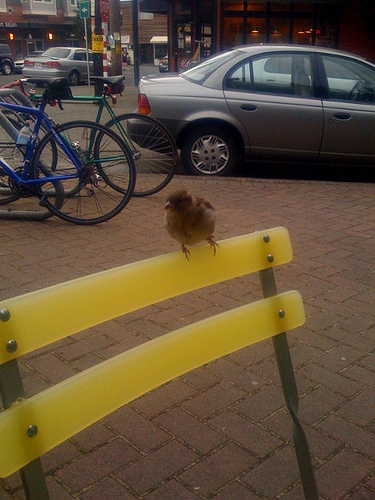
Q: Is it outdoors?
A: Yes, it is outdoors.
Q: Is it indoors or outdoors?
A: It is outdoors.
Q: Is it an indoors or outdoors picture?
A: It is outdoors.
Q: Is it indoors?
A: No, it is outdoors.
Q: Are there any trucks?
A: No, there are no trucks.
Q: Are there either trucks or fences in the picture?
A: No, there are no trucks or fences.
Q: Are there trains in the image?
A: No, there are no trains.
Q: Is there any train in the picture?
A: No, there are no trains.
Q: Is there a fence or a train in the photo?
A: No, there are no trains or fences.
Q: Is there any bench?
A: Yes, there is a bench.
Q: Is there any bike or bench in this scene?
A: Yes, there is a bench.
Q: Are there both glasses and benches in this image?
A: No, there is a bench but no glasses.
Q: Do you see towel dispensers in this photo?
A: No, there are no towel dispensers.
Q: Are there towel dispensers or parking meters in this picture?
A: No, there are no towel dispensers or parking meters.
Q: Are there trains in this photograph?
A: No, there are no trains.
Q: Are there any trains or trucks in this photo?
A: No, there are no trains or trucks.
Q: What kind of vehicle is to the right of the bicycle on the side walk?
A: The vehicle is a car.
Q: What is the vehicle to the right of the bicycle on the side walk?
A: The vehicle is a car.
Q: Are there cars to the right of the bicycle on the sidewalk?
A: Yes, there is a car to the right of the bicycle.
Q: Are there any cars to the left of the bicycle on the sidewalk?
A: No, the car is to the right of the bicycle.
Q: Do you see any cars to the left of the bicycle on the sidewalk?
A: No, the car is to the right of the bicycle.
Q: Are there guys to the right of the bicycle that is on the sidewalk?
A: No, there is a car to the right of the bicycle.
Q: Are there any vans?
A: No, there are no vans.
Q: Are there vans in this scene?
A: No, there are no vans.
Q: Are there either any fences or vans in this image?
A: No, there are no vans or fences.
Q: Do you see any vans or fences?
A: No, there are no vans or fences.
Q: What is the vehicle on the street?
A: The vehicle is a car.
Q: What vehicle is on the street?
A: The vehicle is a car.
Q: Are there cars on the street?
A: Yes, there is a car on the street.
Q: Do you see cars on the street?
A: Yes, there is a car on the street.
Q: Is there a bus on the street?
A: No, there is a car on the street.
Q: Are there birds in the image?
A: Yes, there is a bird.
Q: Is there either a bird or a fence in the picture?
A: Yes, there is a bird.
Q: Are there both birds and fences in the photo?
A: No, there is a bird but no fences.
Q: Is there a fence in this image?
A: No, there are no fences.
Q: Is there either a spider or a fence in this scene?
A: No, there are no fences or spiders.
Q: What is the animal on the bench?
A: The animal is a bird.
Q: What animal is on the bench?
A: The animal is a bird.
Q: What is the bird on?
A: The bird is on the bench.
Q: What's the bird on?
A: The bird is on the bench.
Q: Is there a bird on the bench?
A: Yes, there is a bird on the bench.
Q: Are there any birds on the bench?
A: Yes, there is a bird on the bench.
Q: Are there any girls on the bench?
A: No, there is a bird on the bench.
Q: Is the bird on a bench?
A: Yes, the bird is on a bench.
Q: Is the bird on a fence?
A: No, the bird is on a bench.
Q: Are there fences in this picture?
A: No, there are no fences.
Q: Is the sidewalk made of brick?
A: Yes, the sidewalk is made of brick.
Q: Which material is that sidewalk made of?
A: The sidewalk is made of brick.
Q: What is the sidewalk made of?
A: The sidewalk is made of brick.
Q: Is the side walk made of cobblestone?
A: No, the side walk is made of brick.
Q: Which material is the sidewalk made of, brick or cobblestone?
A: The sidewalk is made of brick.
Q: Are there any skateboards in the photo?
A: No, there are no skateboards.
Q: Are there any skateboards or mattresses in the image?
A: No, there are no skateboards or mattresses.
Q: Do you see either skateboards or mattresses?
A: No, there are no skateboards or mattresses.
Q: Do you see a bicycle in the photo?
A: Yes, there is a bicycle.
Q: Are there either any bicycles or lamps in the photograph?
A: Yes, there is a bicycle.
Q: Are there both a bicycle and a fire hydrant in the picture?
A: No, there is a bicycle but no fire hydrants.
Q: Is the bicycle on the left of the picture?
A: Yes, the bicycle is on the left of the image.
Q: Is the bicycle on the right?
A: No, the bicycle is on the left of the image.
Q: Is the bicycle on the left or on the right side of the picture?
A: The bicycle is on the left of the image.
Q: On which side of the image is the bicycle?
A: The bicycle is on the left of the image.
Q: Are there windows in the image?
A: Yes, there is a window.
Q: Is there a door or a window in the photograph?
A: Yes, there is a window.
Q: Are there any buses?
A: No, there are no buses.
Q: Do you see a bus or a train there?
A: No, there are no buses or trains.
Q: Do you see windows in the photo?
A: Yes, there is a window.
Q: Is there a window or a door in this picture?
A: Yes, there is a window.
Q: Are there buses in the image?
A: No, there are no buses.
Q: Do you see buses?
A: No, there are no buses.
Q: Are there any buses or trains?
A: No, there are no buses or trains.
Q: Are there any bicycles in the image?
A: Yes, there is a bicycle.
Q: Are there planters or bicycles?
A: Yes, there is a bicycle.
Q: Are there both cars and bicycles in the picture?
A: Yes, there are both a bicycle and a car.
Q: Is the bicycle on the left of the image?
A: Yes, the bicycle is on the left of the image.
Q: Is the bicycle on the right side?
A: No, the bicycle is on the left of the image.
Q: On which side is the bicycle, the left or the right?
A: The bicycle is on the left of the image.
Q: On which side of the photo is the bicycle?
A: The bicycle is on the left of the image.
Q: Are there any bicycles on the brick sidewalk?
A: Yes, there is a bicycle on the sidewalk.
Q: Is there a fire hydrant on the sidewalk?
A: No, there is a bicycle on the sidewalk.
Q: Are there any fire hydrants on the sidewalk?
A: No, there is a bicycle on the sidewalk.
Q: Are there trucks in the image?
A: No, there are no trucks.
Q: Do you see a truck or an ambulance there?
A: No, there are no trucks or ambulances.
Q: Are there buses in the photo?
A: No, there are no buses.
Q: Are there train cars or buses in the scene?
A: No, there are no buses or train cars.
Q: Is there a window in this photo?
A: Yes, there is a window.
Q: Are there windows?
A: Yes, there is a window.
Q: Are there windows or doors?
A: Yes, there is a window.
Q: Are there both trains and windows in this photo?
A: No, there is a window but no trains.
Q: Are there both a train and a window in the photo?
A: No, there is a window but no trains.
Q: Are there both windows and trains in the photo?
A: No, there is a window but no trains.